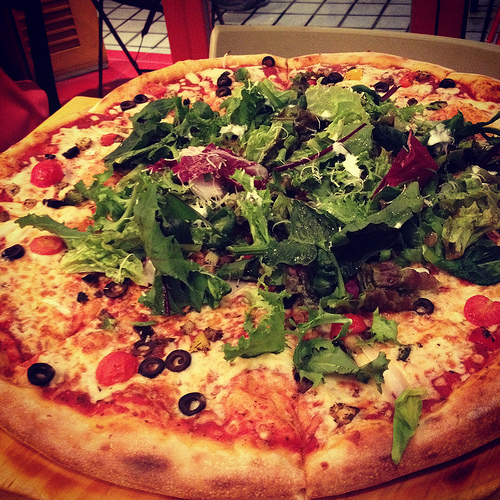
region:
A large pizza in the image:
[0, 50, 497, 490]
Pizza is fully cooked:
[0, 47, 495, 497]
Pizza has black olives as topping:
[141, 338, 217, 423]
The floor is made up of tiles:
[115, 0, 456, 50]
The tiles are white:
[101, 1, 496, 47]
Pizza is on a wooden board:
[1, 423, 498, 497]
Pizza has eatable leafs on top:
[106, 74, 449, 327]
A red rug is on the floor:
[0, 26, 196, 152]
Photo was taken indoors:
[11, 6, 495, 491]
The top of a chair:
[198, 16, 498, 82]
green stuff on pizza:
[258, 152, 360, 256]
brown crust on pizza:
[90, 416, 171, 482]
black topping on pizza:
[163, 337, 191, 383]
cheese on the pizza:
[194, 339, 235, 387]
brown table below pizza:
[14, 463, 53, 495]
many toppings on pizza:
[208, 61, 406, 266]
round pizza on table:
[126, 53, 441, 316]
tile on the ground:
[328, 6, 370, 28]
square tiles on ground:
[264, 5, 355, 22]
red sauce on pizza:
[421, 366, 482, 411]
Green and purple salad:
[117, 53, 452, 338]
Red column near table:
[150, 2, 230, 67]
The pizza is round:
[6, 50, 466, 490]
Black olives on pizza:
[35, 280, 240, 431]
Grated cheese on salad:
[150, 96, 366, 201]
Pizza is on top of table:
[11, 450, 491, 490]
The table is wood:
[2, 415, 482, 490]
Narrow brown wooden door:
[10, 5, 116, 90]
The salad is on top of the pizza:
[48, 56, 493, 424]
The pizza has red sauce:
[21, 69, 231, 192]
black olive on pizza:
[164, 390, 213, 417]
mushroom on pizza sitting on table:
[331, 391, 359, 433]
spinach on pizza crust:
[389, 390, 427, 463]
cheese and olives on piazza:
[143, 342, 282, 424]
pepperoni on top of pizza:
[93, 346, 135, 383]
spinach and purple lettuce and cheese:
[7, 42, 497, 483]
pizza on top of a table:
[7, 13, 494, 494]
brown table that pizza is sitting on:
[1, 430, 497, 496]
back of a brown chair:
[216, 15, 498, 80]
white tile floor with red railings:
[105, 4, 497, 52]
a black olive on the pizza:
[258, 49, 278, 70]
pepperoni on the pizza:
[92, 343, 139, 395]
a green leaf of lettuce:
[384, 381, 429, 473]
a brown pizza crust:
[0, 375, 310, 498]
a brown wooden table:
[0, 423, 498, 498]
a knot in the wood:
[437, 453, 482, 493]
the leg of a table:
[163, 0, 220, 62]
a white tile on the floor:
[346, 0, 387, 20]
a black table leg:
[97, 7, 146, 75]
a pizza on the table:
[0, 48, 499, 498]